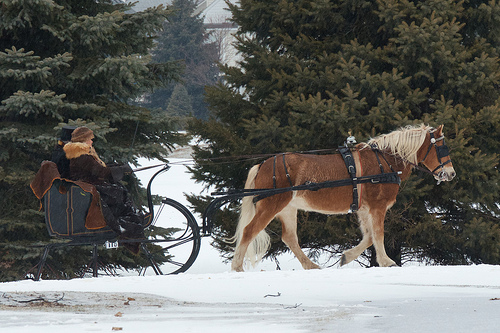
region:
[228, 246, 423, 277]
Horse walking on snow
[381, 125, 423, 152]
white long hair on horse neck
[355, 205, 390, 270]
front leg of horse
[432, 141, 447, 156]
black flap on horse eye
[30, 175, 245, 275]
horse tied to cart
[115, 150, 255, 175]
person holding rope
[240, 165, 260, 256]
long tail of horse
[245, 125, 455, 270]
brown horse with white hair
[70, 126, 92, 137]
person wearing brown furry cap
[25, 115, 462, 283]
a horse drawn sled in the snow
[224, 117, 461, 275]
the horse pulling the sled is brown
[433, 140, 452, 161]
the horse is wearing blinders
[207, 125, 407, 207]
the horse is wearing a black harness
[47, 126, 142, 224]
two passengers sit in the sled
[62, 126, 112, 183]
one sled rider is wearing a fur-collared coat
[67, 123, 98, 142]
the lady with the fur coat also has a fur hat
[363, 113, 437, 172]
the horse's mane is beige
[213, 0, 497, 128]
no snow on the trees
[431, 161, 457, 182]
the horse's nose is white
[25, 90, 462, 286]
horse pulling carriage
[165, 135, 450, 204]
black harnass on horse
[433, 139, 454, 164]
black blinder over horse eye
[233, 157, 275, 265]
blonde tail of horse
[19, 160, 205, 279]
green carriage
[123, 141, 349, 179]
reigns attached to horse harnass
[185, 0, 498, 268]
tall green evergreen tree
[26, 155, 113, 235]
brown piece of fabric inside of carriage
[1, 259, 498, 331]
white snow covered ground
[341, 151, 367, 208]
metal buckles on black harnass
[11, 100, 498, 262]
horse pulling a sleigh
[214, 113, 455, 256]
horse in front of sleigh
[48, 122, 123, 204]
people riding in the sleigh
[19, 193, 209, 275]
gliders on the sleigh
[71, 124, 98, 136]
hat on sleigh rider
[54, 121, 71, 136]
hat on sleigh rider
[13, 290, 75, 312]
twig on the ground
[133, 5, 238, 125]
tree in the distance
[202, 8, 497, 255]
tree near the horse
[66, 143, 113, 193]
coat on sleigh rider